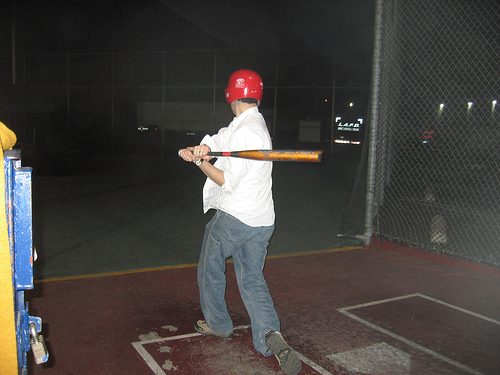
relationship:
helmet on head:
[211, 48, 290, 135] [211, 50, 302, 159]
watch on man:
[191, 145, 237, 172] [167, 68, 359, 354]